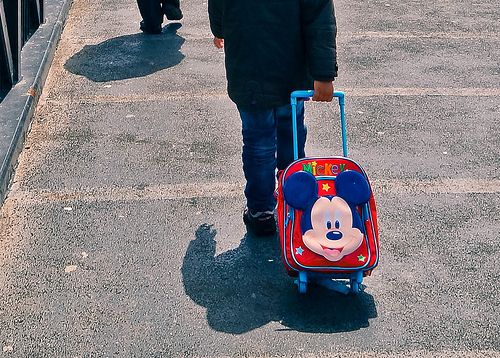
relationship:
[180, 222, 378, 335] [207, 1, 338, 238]
shadow of person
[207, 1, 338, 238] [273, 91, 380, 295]
person rolling backpack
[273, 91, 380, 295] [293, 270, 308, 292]
backpack with wheel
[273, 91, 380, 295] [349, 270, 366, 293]
backpack with wheel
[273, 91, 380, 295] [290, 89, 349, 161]
backpack with handle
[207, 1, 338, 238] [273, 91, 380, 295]
person pulling backpack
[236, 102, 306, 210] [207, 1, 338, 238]
pants of person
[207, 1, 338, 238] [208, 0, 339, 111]
person wearing jacket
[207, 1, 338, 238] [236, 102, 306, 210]
person wearing pants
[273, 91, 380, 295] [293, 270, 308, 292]
backpack on wheel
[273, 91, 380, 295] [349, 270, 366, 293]
backpack on wheel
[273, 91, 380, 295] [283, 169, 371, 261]
backpack has mickey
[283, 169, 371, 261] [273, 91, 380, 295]
mickey on backpack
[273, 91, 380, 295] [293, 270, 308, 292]
backpack has wheel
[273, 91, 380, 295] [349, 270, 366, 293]
backpack has wheel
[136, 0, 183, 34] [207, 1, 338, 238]
man walking in front of person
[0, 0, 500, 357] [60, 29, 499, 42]
pavement has line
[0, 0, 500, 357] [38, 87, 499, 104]
pavement has line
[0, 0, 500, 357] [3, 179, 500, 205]
pavement has line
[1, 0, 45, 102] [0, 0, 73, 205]
fence on curb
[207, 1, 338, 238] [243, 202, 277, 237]
person has on sneaker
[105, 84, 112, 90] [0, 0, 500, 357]
spot on pavement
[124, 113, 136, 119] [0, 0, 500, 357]
spot on pavement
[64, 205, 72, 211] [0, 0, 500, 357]
spot on pavement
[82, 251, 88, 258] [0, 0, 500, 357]
spot on pavement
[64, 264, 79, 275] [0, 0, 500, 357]
spot on pavement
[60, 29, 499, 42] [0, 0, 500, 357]
line on pavement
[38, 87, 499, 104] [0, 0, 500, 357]
line on pavement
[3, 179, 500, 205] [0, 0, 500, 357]
line on pavement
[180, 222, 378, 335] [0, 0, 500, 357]
shadow on pavement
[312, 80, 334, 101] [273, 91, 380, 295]
hand on backpack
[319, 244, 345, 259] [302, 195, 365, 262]
grin on face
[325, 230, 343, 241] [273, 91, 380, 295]
nose on backpack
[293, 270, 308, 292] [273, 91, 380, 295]
wheel on backpack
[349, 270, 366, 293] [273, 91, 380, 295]
wheel on backpack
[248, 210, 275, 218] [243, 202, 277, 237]
edge of sneaker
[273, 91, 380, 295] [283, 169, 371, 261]
backpack with mickey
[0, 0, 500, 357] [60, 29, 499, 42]
pavement with line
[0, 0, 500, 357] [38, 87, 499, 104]
pavement with line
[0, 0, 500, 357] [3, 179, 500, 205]
pavement with line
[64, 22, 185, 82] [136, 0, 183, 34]
shadow of man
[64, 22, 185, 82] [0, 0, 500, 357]
shadow on pavement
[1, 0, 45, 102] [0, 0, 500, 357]
fence on pavement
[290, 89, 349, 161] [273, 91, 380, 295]
handle on backpack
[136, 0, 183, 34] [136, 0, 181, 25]
man wearing pants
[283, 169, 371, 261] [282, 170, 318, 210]
mickey with ear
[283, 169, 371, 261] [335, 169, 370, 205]
mickey with ear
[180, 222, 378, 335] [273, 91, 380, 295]
shadow of backpack